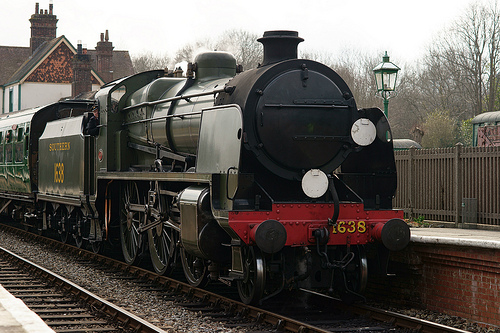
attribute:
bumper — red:
[228, 202, 408, 248]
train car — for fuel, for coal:
[35, 23, 420, 307]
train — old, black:
[2, 31, 414, 303]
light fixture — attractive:
[374, 51, 402, 101]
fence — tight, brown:
[384, 142, 500, 229]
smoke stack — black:
[258, 31, 305, 65]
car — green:
[1, 105, 44, 234]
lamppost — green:
[375, 52, 399, 123]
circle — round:
[350, 117, 377, 146]